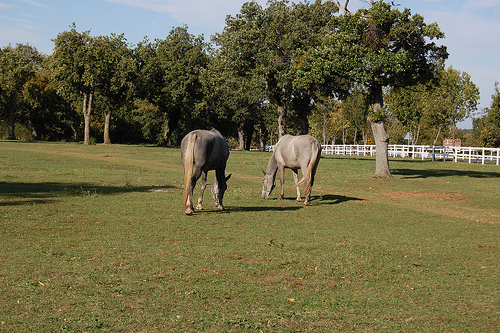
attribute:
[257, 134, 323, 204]
horse — gray, eating, grey, grazing, brown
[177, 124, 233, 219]
horse — gray, eating, grazing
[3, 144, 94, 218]
grass — green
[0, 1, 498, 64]
sky — blue, clear, cloudy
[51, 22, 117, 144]
tree — green, big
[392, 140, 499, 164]
fence — white, wooden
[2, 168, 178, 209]
shadow — dark, cast, large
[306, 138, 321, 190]
tail — blonde, long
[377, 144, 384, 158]
bark — gray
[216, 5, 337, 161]
tree — tall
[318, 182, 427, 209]
pathway — made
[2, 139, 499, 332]
field — green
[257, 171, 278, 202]
head — down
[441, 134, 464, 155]
building — distant